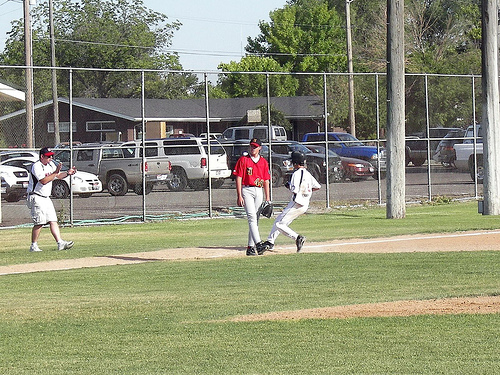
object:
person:
[235, 137, 269, 258]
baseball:
[260, 203, 275, 220]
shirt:
[232, 155, 274, 186]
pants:
[239, 185, 266, 246]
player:
[260, 151, 322, 252]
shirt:
[285, 169, 321, 207]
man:
[25, 145, 77, 251]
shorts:
[28, 191, 59, 227]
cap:
[38, 145, 55, 157]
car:
[123, 143, 234, 196]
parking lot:
[1, 125, 490, 204]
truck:
[303, 130, 389, 183]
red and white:
[235, 136, 271, 258]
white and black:
[264, 153, 322, 252]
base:
[237, 244, 279, 257]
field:
[0, 198, 269, 252]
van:
[216, 126, 288, 146]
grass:
[0, 252, 500, 373]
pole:
[386, 0, 406, 222]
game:
[228, 137, 322, 258]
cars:
[304, 132, 388, 181]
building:
[0, 94, 356, 148]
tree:
[0, 1, 194, 100]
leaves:
[108, 0, 182, 47]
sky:
[163, 3, 264, 93]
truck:
[55, 141, 170, 194]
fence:
[0, 65, 483, 227]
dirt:
[405, 241, 459, 251]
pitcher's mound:
[152, 242, 224, 263]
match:
[28, 138, 321, 254]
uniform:
[234, 152, 270, 242]